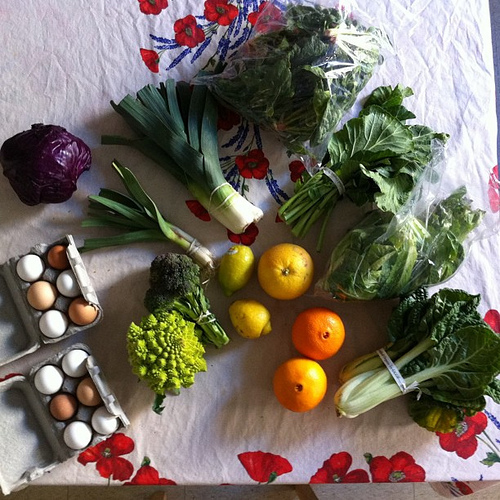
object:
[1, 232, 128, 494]
two cartons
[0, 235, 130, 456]
eggs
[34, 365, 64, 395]
egg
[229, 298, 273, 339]
lime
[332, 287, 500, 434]
vegetable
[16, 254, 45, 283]
egg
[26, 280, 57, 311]
egg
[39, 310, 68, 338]
egg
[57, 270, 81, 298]
egg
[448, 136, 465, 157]
ground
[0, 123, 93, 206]
cabbage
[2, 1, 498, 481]
table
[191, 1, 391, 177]
chard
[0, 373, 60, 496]
egg carton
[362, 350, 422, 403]
rubber band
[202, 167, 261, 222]
rubber band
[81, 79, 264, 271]
leeks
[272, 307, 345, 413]
navel oranges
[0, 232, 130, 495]
egg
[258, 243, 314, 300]
grapefruit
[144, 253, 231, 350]
broccoli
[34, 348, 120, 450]
eggs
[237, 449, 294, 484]
flower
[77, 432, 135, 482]
flower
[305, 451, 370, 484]
flower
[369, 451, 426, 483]
flower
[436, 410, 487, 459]
flower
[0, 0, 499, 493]
woman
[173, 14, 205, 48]
flowers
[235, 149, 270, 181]
flowers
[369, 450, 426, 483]
flowers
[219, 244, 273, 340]
lemons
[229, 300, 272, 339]
lemon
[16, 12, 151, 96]
tablecloth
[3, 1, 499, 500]
tablecloth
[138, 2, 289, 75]
poppies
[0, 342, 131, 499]
carton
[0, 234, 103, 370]
carton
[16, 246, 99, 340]
eggs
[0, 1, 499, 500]
cloth